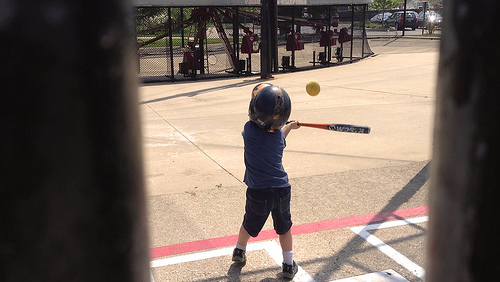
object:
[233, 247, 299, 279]
shoes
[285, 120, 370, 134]
baseball bat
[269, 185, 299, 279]
leg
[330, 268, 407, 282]
white lines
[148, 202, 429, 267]
line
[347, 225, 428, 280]
line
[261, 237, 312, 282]
line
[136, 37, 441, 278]
concrete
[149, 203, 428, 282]
box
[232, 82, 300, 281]
batter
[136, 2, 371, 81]
fence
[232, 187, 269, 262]
leg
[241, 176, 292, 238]
shorts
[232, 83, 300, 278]
boy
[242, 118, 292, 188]
shirt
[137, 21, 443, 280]
ground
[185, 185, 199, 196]
plant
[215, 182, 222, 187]
plant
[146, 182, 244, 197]
crack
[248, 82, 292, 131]
helmet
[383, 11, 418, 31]
vehicle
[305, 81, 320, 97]
ball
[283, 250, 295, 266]
sock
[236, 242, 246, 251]
sock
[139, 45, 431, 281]
court